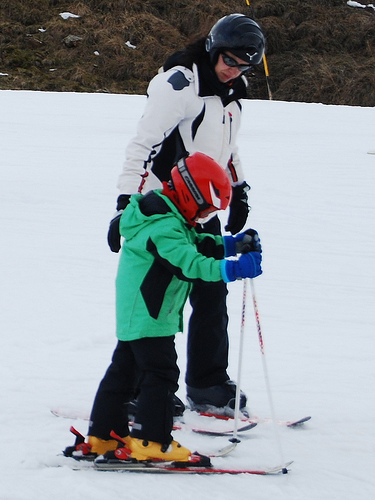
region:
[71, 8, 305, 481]
a woman and a kid wearing skis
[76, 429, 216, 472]
yellow ski boots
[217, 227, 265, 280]
blue gloves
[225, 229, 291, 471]
kid holding ski poles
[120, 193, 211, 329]
kid wearing a green and black coat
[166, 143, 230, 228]
kid wearing a red helmet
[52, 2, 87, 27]
snow on a rock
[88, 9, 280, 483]
woman helping a kid to learn to ski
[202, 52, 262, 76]
black sunglasses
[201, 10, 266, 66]
a black helmet on woman's head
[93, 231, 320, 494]
child is holding ski poles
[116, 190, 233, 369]
child's jacket is green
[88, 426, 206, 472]
child's ski boots are yellow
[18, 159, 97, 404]
the ground is covered with snow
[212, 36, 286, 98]
woman is wearing sunglasses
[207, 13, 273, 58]
woman's helmet is black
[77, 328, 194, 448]
child's ski pants are black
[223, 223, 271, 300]
child's gloves are blue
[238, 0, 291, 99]
yellow and black pole in the snow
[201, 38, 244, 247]
woman is looking at child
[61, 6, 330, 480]
an adult helping a child to ski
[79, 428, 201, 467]
the yellow ski boots of the child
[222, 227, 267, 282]
the child's blue ski gloves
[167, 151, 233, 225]
the child's red ski helmet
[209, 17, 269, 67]
the adult's black ski helmet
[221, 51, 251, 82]
the adult's black sunglasses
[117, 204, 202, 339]
the bright green ski jacket the child is wearing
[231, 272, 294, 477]
two white ski poles the child is using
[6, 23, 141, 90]
a brown grassy area with no snow nearby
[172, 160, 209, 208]
a grey and black stripe on the child's red helmet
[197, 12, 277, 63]
Black helmet on woman's head.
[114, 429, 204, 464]
Yellow snow shoes.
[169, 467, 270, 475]
Red strip on ski.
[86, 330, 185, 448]
The boy wears black pants.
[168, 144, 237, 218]
Red helmet on the boy's head.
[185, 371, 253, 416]
Black snow shoes on the woman's feet.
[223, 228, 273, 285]
Blue gloves on the boy's hands.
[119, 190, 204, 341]
Green and black blazer.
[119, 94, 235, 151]
Lady wears a white jacket.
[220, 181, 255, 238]
Black gloves on the woman's hands.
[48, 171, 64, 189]
Small patch of snow in the ground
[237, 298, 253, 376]
Right red and white ski pole of little kid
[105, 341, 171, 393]
Black pants of little kid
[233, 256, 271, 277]
Right blue glove of little kid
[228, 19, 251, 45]
Black helmet of adult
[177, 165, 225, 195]
Red helmet of adult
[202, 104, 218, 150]
Small part of white jacket of the adult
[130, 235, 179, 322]
Light green and black sweater of the little kid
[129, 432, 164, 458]
Right yellow shoes of the little kid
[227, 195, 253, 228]
Left black glove of adult